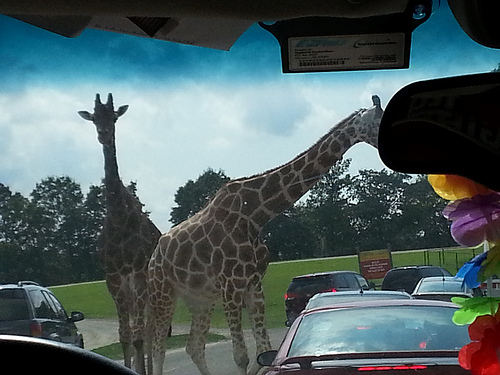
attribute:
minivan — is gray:
[2, 268, 92, 355]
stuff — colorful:
[425, 170, 499, 373]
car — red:
[261, 286, 487, 372]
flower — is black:
[425, 174, 493, 201]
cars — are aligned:
[266, 269, 464, 372]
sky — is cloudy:
[151, 84, 280, 160]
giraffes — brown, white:
[73, 72, 405, 372]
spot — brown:
[170, 240, 195, 270]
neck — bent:
[232, 118, 348, 236]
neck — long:
[243, 132, 360, 223]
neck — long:
[91, 141, 131, 226]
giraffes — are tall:
[77, 90, 379, 372]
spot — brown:
[275, 173, 299, 201]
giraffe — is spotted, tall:
[77, 93, 168, 373]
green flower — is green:
[449, 292, 490, 326]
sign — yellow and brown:
[358, 247, 396, 279]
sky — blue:
[2, 0, 499, 250]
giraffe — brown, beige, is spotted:
[146, 95, 384, 374]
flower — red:
[441, 203, 498, 257]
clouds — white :
[2, 27, 91, 180]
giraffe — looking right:
[68, 87, 387, 319]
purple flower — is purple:
[443, 195, 497, 249]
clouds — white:
[300, 96, 327, 128]